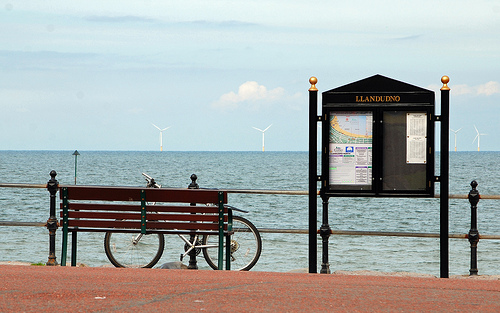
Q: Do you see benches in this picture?
A: Yes, there is a bench.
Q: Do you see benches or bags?
A: Yes, there is a bench.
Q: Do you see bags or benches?
A: Yes, there is a bench.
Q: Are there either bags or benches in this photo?
A: Yes, there is a bench.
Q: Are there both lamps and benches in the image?
A: No, there is a bench but no lamps.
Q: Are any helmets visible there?
A: No, there are no helmets.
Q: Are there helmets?
A: No, there are no helmets.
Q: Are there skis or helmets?
A: No, there are no helmets or skis.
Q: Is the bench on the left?
A: Yes, the bench is on the left of the image.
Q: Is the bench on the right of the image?
A: No, the bench is on the left of the image.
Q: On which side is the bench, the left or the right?
A: The bench is on the left of the image.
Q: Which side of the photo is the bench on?
A: The bench is on the left of the image.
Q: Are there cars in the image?
A: No, there are no cars.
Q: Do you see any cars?
A: No, there are no cars.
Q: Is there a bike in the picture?
A: Yes, there is a bike.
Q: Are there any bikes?
A: Yes, there is a bike.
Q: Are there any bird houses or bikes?
A: Yes, there is a bike.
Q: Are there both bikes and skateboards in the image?
A: No, there is a bike but no skateboards.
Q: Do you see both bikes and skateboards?
A: No, there is a bike but no skateboards.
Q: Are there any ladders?
A: No, there are no ladders.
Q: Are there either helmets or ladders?
A: No, there are no ladders or helmets.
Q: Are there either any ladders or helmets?
A: No, there are no ladders or helmets.